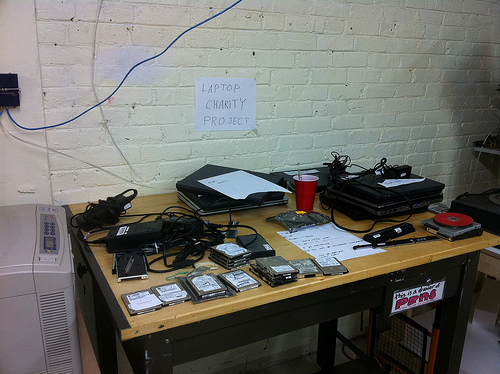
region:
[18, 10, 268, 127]
a blue cord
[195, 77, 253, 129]
a sign on the wall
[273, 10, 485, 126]
white bricks on the wall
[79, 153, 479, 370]
a table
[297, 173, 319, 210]
a red plastic cup on the table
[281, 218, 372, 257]
papers on the table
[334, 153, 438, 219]
laptops on the table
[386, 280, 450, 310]
a sign on the table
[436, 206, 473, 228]
a red CD on the table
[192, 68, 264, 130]
Laptop charity sign on the wall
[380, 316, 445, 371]
A basket under neath the table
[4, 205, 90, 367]
A copy machine next to the table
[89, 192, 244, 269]
Chargers stacked up on the table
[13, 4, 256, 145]
A blue wire running down the wall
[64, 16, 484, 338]
A white brick wall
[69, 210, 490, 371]
A table full of electronics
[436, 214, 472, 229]
A red CD on the table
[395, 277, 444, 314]
A sticker on the edge of the table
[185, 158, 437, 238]
Laptops that are on the table stacked up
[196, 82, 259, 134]
a paper on the wall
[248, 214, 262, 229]
a desk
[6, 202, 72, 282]
a printer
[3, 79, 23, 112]
an adapter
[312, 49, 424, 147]
the bricks on the wall are white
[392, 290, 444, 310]
a sign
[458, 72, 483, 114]
a shadow on the wall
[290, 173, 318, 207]
a red cup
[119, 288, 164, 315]
an internal hard drive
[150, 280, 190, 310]
an internal hard drive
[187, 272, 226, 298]
an internal hard drive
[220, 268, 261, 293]
an internal hard drive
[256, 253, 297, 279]
an internal hard drive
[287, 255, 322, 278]
an internal hard drive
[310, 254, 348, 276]
an internal hard drive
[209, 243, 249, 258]
an internal hard drive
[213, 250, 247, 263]
an internal hard drive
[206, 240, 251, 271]
a stack of hard drive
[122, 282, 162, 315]
a computer hard drive on a table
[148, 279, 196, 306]
a computer hard drive on a table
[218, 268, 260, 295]
a computer hard drive on a table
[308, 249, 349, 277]
a computer hard drive on a table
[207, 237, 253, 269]
a stack of hard drives on a table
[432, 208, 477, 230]
a stack of cds on a table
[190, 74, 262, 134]
a paper saying laptop charity project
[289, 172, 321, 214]
a red cup on a table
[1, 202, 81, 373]
a printer by a table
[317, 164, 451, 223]
a stack of electronic equipment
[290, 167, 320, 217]
A red Plastic cup on the table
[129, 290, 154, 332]
a disk on the desk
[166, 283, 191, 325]
a disk on the desk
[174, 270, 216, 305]
a disk on the desk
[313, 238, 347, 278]
a disk on the desk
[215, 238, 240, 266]
a disk on the desk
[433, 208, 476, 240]
a disk on the desk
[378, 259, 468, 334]
a sticker on the desk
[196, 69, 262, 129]
sign on the wall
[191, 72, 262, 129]
sign is white in color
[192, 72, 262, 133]
sign has text on it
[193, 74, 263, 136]
sign has black text on it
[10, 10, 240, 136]
cord against the wall